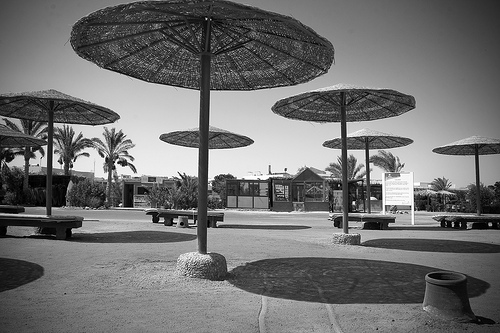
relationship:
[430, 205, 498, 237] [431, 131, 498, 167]
bench has umbrella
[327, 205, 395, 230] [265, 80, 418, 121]
bench has umbrella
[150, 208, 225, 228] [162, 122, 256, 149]
bench has umbrella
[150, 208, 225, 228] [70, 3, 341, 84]
bench has umbrella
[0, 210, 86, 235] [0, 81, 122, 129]
bench has umbrella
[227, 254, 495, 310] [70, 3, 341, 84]
shadow from umbrella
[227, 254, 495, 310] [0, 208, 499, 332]
shadow on concrete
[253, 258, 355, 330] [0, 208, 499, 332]
lines on concrete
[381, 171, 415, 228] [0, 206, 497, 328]
sign on patio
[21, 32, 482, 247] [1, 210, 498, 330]
umbrellas are around area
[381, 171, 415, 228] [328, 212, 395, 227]
sign behind bench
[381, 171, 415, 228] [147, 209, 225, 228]
sign behind bench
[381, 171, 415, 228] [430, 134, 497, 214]
sign behind umbrella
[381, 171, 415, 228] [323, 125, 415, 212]
sign behind umbrella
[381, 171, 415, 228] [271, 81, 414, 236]
sign behind umbrella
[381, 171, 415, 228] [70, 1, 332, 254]
sign behind umbrella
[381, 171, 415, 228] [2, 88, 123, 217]
sign behind umbrella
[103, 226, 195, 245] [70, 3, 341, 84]
shadow cast by umbrella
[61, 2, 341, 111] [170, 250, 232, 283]
umbrella has stand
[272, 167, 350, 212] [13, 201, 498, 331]
buidings behind park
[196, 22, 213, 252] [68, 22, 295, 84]
pole on umbrella